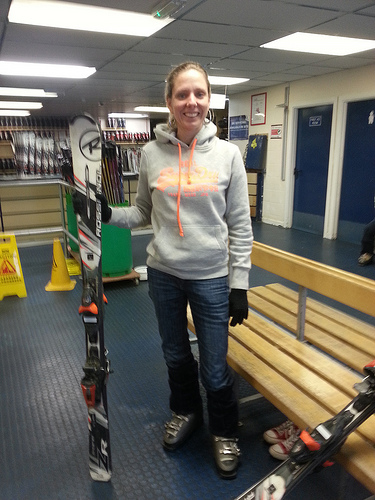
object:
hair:
[160, 56, 209, 133]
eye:
[192, 88, 207, 100]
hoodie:
[100, 126, 270, 288]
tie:
[168, 137, 201, 251]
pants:
[139, 258, 251, 444]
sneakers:
[210, 410, 242, 476]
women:
[94, 59, 254, 482]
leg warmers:
[203, 376, 239, 440]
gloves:
[225, 285, 252, 328]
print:
[147, 164, 225, 203]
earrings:
[203, 109, 212, 125]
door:
[287, 100, 331, 237]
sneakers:
[267, 427, 310, 466]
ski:
[66, 111, 113, 482]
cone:
[42, 236, 78, 290]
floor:
[3, 218, 375, 500]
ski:
[228, 357, 374, 499]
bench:
[183, 236, 375, 500]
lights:
[3, 1, 194, 46]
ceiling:
[0, 1, 374, 136]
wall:
[225, 81, 295, 226]